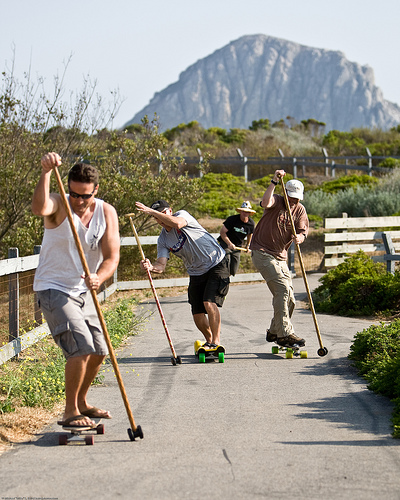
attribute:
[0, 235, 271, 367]
small fence — wooden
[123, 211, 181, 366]
pole — wooden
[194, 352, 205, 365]
wheel — green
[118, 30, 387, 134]
mountain — large, white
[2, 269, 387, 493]
path — paved, asphalt